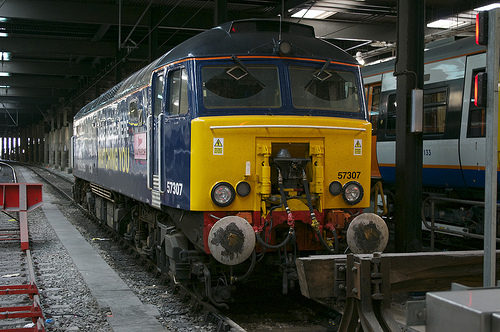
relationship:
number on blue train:
[334, 167, 362, 180] [66, 16, 388, 313]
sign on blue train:
[128, 130, 150, 163] [66, 16, 388, 313]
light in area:
[283, 2, 352, 31] [281, 5, 485, 138]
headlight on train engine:
[344, 180, 362, 202] [65, 12, 389, 301]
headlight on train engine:
[210, 181, 237, 207] [65, 12, 389, 301]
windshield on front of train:
[160, 57, 372, 116] [37, 19, 409, 313]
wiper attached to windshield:
[202, 46, 287, 107] [160, 57, 372, 116]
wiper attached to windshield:
[282, 55, 367, 125] [160, 57, 372, 116]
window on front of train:
[160, 73, 197, 120] [17, 19, 427, 306]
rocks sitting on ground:
[24, 215, 104, 330] [2, 164, 228, 329]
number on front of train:
[335, 170, 361, 180] [40, 15, 375, 309]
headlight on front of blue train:
[344, 182, 361, 203] [66, 16, 388, 313]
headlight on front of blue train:
[207, 180, 237, 205] [66, 16, 388, 313]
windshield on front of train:
[159, 51, 373, 131] [37, 25, 410, 278]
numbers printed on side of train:
[164, 178, 187, 197] [67, 22, 397, 244]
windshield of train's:
[160, 57, 372, 116] [3, 15, 497, 312]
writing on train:
[94, 143, 130, 172] [75, 16, 389, 276]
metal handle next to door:
[155, 116, 169, 191] [145, 64, 173, 212]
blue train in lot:
[66, 16, 388, 313] [0, 2, 497, 329]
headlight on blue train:
[210, 181, 237, 207] [66, 16, 388, 313]